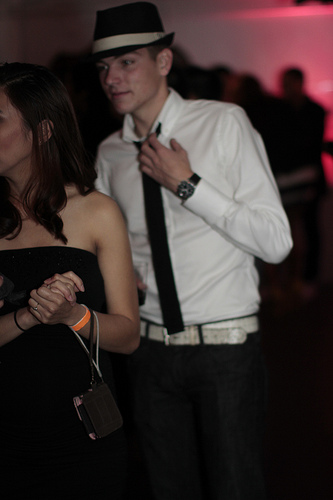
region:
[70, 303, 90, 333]
orange club sticker bracelet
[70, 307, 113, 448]
cell phone hanging from girl's wrist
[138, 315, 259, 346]
large white belt on boy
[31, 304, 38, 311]
ring on girl's finger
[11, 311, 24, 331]
black rubber band around girl's wrist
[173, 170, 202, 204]
large black watch on man's hand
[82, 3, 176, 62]
black fedora hat with white band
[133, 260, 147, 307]
beverage in boy's hand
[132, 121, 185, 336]
black tie around boy's neck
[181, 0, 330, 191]
sihouette of crowd in front of pink light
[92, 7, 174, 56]
brown and tan trilby hat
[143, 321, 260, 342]
white leather belt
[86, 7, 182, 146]
young man in fedora hat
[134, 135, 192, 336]
long skinny black neck tie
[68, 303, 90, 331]
a bright orange bracelet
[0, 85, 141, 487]
young woman in night club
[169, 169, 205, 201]
black analog wrist watch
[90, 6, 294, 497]
young man wearing white shirt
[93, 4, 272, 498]
young man in semi-formal attire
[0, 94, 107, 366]
young woman in black dress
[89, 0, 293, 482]
boy wearing white shirt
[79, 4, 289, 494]
boy wearing white belt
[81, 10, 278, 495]
boy wearing black hat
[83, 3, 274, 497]
boy wearing denim jeans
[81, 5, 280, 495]
boy wearing black tie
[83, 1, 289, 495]
boy wearing wrist watch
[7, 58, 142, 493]
girl wearing orange bracelet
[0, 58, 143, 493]
girl wearing black dress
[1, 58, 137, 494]
girl wearing metal ring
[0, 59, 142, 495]
girl has brown hair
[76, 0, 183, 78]
black and white fedora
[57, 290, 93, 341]
bright orange wrist band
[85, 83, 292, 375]
white button down dress shirt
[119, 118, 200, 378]
long black neck tie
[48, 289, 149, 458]
small black wristlet purse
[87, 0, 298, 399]
young thin white male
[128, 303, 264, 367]
shiny white leather belt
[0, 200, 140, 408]
strapless black women's top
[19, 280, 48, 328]
silver ring on left ring finger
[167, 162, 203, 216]
large face men's wristwatch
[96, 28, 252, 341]
boy having fun at school dance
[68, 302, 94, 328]
orange wrist band for entrance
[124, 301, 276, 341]
white belt on young man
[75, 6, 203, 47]
hat on top of boy's head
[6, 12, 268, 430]
couple having fun at school dance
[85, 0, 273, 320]
boy having fun at dance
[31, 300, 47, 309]
ring on girl's finger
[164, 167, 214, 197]
watch on boy's wrist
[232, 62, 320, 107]
other people dancing in background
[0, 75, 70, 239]
half of girl's face at dance